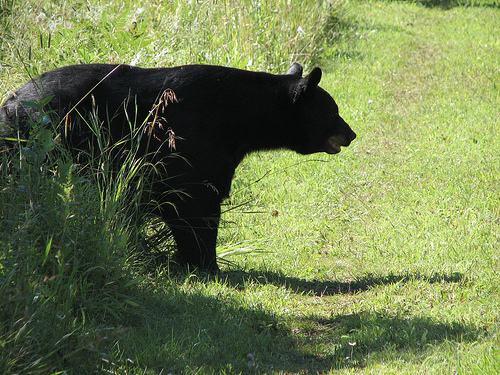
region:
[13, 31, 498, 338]
the bear has black fur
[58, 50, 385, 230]
the bear has black fur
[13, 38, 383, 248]
bear is black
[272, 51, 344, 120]
bear has black ears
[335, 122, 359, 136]
bear has black nose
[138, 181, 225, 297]
bear has black legs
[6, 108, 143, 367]
green reedy grass next to bear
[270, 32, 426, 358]
brown tracks in grass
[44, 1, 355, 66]
tall grass behind bear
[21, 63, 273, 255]
bear has black fur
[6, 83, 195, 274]
wispy grass in front of bear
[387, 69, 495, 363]
grass is short next to bear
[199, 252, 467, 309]
shadow of the bear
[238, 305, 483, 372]
shadow of the grass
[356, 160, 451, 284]
field bear is going to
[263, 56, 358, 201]
head of the bear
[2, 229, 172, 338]
long grass in field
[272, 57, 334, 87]
ears of the bear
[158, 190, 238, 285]
bear's front legs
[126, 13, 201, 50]
white flowers in the grass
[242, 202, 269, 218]
blade of the grass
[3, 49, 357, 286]
bear standing in field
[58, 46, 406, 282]
black bear on grass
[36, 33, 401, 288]
black bear in grassy field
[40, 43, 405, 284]
one black bear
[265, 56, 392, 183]
black bears face looking curious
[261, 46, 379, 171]
black bear with teeth showing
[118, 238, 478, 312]
shadow of a bear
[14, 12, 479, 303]
bear with sun behind casting his shadow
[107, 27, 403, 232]
bear with ears perched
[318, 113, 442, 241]
green grass and a bear snout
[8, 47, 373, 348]
tall weeds by a bear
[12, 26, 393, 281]
the bear is black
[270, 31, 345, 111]
bear's ears pointed upwards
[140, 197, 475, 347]
shadow of bear on grass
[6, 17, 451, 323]
bear is standing on grass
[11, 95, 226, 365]
long grass next to bear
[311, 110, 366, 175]
the bear's mouth is brown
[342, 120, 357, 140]
the bear's nose is black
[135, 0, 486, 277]
sun is shining on grass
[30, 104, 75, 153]
blue flower on plant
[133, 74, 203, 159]
part of plant is brown